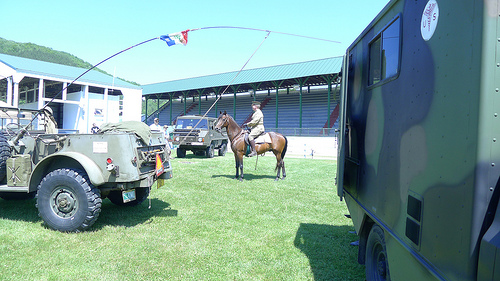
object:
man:
[245, 100, 265, 157]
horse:
[213, 113, 289, 181]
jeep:
[1, 106, 177, 233]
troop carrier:
[333, 0, 500, 281]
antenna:
[11, 26, 343, 155]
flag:
[160, 29, 193, 46]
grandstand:
[143, 89, 344, 135]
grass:
[0, 221, 288, 278]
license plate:
[119, 189, 140, 203]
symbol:
[416, 1, 440, 42]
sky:
[0, 0, 370, 77]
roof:
[138, 56, 342, 95]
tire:
[35, 168, 104, 232]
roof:
[0, 54, 142, 89]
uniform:
[248, 109, 266, 141]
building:
[0, 54, 145, 134]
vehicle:
[172, 115, 229, 159]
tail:
[282, 134, 288, 163]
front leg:
[234, 152, 245, 181]